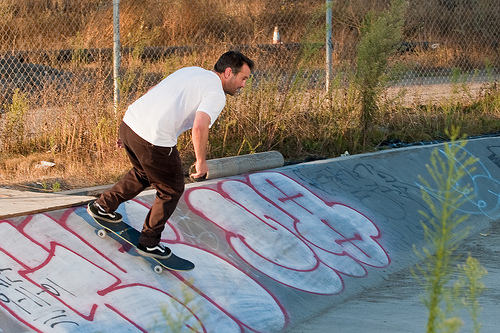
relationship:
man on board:
[87, 51, 254, 259] [87, 202, 195, 275]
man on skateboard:
[87, 51, 254, 259] [73, 192, 203, 277]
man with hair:
[87, 51, 254, 259] [214, 42, 251, 85]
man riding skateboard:
[87, 51, 254, 259] [83, 190, 209, 286]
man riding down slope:
[87, 51, 254, 259] [3, 139, 496, 332]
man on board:
[87, 51, 254, 259] [77, 176, 223, 273]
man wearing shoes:
[141, 44, 282, 224] [88, 197, 171, 257]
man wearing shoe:
[87, 51, 254, 259] [137, 237, 170, 257]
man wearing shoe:
[87, 51, 254, 259] [84, 199, 124, 221]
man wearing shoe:
[87, 51, 254, 259] [142, 238, 170, 258]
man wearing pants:
[87, 51, 254, 259] [99, 120, 184, 239]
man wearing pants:
[87, 51, 254, 259] [95, 117, 185, 247]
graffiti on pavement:
[231, 166, 372, 318] [0, 138, 499, 331]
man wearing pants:
[87, 51, 254, 259] [93, 121, 186, 241]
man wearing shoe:
[87, 51, 254, 259] [136, 243, 173, 258]